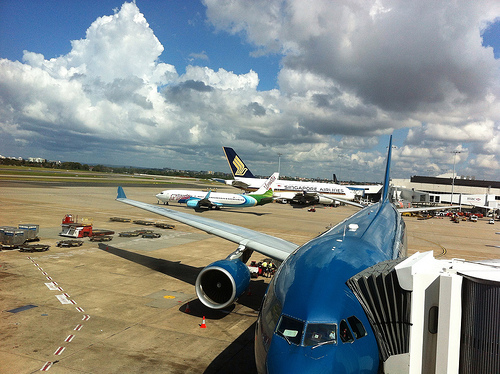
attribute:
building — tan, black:
[401, 174, 498, 209]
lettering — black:
[282, 183, 344, 194]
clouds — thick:
[0, 0, 499, 183]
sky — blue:
[0, 0, 500, 184]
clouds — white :
[5, 3, 496, 129]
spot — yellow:
[125, 277, 206, 332]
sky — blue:
[5, 6, 52, 43]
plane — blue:
[114, 149, 416, 371]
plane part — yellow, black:
[222, 141, 257, 176]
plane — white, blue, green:
[128, 101, 320, 258]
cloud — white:
[21, 1, 164, 80]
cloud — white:
[184, 47, 211, 63]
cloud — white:
[200, 1, 484, 118]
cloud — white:
[332, 133, 381, 147]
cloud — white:
[287, 1, 485, 118]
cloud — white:
[200, 1, 283, 57]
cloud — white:
[274, 65, 341, 96]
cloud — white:
[399, 119, 473, 142]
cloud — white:
[79, 75, 156, 116]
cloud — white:
[22, 0, 162, 90]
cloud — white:
[149, 60, 179, 90]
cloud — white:
[46, 1, 165, 90]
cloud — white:
[18, 48, 46, 68]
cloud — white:
[1, 56, 192, 145]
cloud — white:
[151, 54, 178, 90]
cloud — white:
[43, 0, 163, 85]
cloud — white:
[0, 57, 170, 141]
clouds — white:
[209, 2, 494, 154]